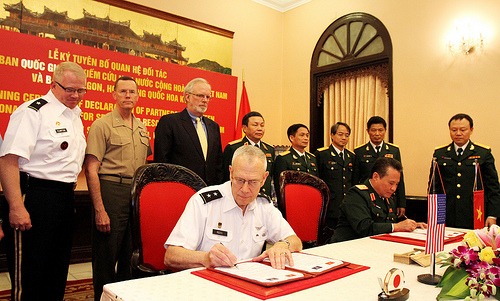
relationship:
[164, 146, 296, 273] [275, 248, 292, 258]
man wearing ring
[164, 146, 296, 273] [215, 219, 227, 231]
man has patch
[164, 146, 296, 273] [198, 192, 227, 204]
man has patch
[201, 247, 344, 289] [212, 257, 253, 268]
papers being signed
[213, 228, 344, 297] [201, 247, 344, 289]
book of papers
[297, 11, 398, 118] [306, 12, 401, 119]
set of wall mirrors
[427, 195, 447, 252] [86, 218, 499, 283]
flag on table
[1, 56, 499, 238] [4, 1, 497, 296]
diplomats in room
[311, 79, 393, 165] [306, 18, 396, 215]
curtain on door opening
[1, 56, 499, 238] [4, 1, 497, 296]
military officials in room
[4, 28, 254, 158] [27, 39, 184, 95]
sign in foreign language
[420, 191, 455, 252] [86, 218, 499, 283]
flag on table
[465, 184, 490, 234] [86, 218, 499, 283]
flag on table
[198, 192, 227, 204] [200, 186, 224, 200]
patch has two stars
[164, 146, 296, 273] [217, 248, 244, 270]
man writing with pen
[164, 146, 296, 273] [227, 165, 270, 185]
man wearing glasses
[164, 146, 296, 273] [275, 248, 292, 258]
man has ring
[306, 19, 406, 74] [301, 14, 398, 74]
top of widow